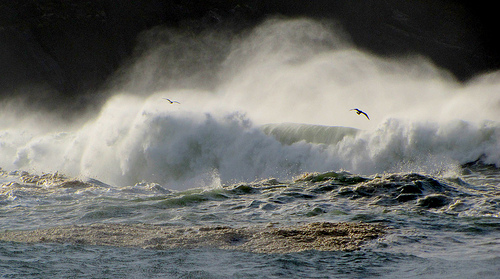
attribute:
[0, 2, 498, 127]
sky — blue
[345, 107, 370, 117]
bird — flying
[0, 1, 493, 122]
clouds — white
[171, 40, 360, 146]
clouds — white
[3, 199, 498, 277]
waters — calm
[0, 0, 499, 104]
sky — dark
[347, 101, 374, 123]
bird — flying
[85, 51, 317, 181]
water — white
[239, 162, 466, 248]
water — churning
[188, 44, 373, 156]
clouds — white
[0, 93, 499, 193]
wave — white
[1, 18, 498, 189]
wave — large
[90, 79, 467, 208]
splash — white 